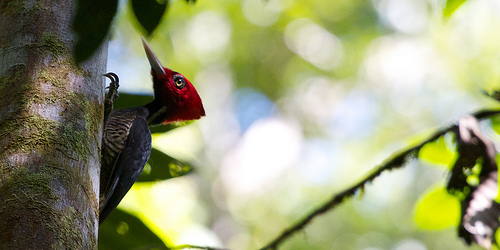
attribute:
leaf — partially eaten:
[134, 144, 196, 194]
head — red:
[151, 68, 204, 120]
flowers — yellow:
[417, 127, 482, 241]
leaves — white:
[449, 116, 498, 218]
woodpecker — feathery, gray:
[114, 71, 206, 196]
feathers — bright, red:
[121, 106, 186, 125]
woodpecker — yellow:
[97, 32, 204, 222]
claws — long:
[92, 73, 125, 190]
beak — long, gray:
[141, 35, 164, 79]